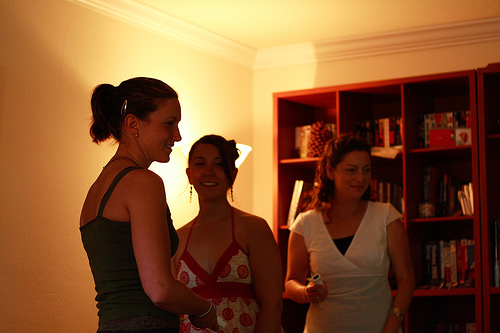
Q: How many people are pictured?
A: Three.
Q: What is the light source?
A: A lamp.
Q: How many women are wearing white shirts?
A: One.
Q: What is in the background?
A: A bookshelf.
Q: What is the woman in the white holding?
A: A wii controller.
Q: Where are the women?
A: In a living room.